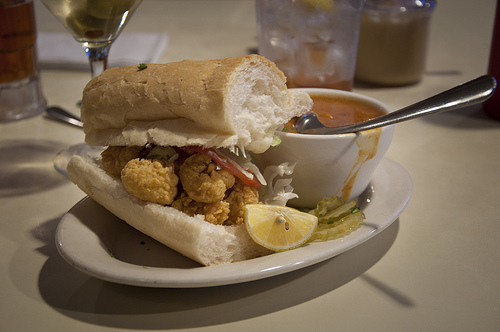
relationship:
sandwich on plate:
[66, 54, 314, 267] [55, 153, 413, 289]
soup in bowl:
[289, 92, 383, 131] [243, 86, 398, 208]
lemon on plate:
[242, 201, 317, 251] [55, 153, 413, 289]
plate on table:
[55, 153, 413, 289] [2, 1, 499, 328]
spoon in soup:
[296, 72, 496, 136] [289, 92, 383, 131]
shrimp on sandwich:
[122, 157, 178, 204] [66, 54, 314, 267]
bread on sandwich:
[81, 53, 315, 152] [66, 54, 314, 267]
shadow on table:
[36, 216, 415, 331] [2, 1, 499, 328]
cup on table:
[254, 0, 363, 96] [2, 1, 499, 328]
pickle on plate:
[310, 195, 364, 242] [55, 153, 413, 289]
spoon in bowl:
[296, 72, 496, 136] [243, 86, 398, 208]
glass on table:
[39, 0, 145, 180] [2, 1, 499, 328]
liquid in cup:
[0, 0, 38, 82] [2, 0, 50, 124]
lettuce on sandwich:
[231, 149, 299, 208] [66, 54, 314, 267]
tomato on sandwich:
[196, 144, 261, 189] [66, 54, 314, 267]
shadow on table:
[0, 137, 75, 197] [2, 1, 499, 328]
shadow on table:
[422, 82, 498, 128] [2, 1, 499, 328]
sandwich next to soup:
[66, 54, 314, 267] [289, 92, 383, 131]